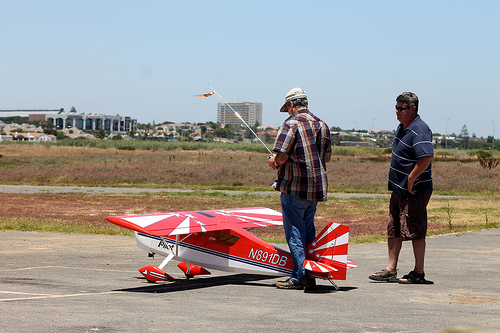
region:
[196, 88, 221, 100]
A plane in the air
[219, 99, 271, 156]
a remote controlled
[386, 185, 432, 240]
a brown pair of shorts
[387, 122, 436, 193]
a blue striped shirt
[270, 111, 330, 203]
a checkered shirt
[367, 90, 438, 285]
a man standing on right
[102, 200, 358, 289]
a model plane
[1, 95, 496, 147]
the city view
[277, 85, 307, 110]
a tan hat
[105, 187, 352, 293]
a small remote control air plane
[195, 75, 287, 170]
a remote control with long antenna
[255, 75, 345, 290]
a man wearing a hat, jeans, and a short sleeve shirt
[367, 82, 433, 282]
a man wearing a blue and white stripped shirt and brown pants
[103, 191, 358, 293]
a red and white model aircraft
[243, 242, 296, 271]
white letters that say N891DB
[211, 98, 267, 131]
a tall high rise seen off in the distance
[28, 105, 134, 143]
a white building seen off in the distance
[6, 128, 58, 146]
a white building with orange roof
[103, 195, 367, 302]
small red and white toy plane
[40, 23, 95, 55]
white clouds in blue sky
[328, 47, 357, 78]
white clouds in blue sky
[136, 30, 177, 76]
white clouds in blue sky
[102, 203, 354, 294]
the airplane is red and white.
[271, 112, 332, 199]
the man is wearing a checkered shirt.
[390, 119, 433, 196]
the man is wearing a striped shirt.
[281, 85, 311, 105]
the man has on a white cap.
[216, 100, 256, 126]
building in the background.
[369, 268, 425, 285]
the man is wearing brown shoes.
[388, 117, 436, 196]
the man's shirt is blue with white stripes.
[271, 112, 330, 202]
the man's shirt is blue, white and yellow.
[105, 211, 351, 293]
the airplane is on the ground.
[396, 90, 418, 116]
the man has dark hair.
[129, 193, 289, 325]
red and white remote control plane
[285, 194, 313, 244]
man wearing blue jeans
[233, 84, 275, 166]
man holding remote control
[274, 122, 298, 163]
man wearing plaid shirt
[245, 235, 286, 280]
numbers on red and white plane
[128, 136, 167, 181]
brown and green grass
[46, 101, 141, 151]
white building in back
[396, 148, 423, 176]
man wearing blue shirt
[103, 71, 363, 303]
A man with the most control airplane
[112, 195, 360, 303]
The toy airplane is red and white.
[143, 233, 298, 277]
The toy airplane has blue stripes on the side.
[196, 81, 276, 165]
The man is holding a control for the toy airplane.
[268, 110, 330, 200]
The man is wearing a plaid shirt.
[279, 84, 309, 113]
The man is wearing a hat.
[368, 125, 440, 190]
The man is wearing a striped shirt.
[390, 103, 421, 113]
The man is wearing sun glasses.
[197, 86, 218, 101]
There is a flag at the end of the pole.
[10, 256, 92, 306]
Faded lines are painted on the ground.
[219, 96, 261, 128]
A tall building is off in the distance.